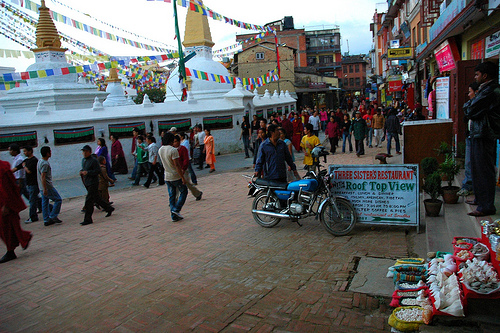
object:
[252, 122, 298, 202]
man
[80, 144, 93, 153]
cap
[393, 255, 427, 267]
bags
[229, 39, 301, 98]
building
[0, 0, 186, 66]
sky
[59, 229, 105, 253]
walkway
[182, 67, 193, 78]
banners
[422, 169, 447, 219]
display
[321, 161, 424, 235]
sign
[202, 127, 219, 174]
woman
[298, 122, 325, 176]
boy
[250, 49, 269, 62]
window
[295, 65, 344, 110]
buildings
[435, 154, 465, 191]
plants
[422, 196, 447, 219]
pots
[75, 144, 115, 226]
men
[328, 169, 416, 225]
poster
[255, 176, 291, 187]
seat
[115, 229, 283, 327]
floor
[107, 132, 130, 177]
people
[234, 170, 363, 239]
motorbike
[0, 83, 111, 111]
squares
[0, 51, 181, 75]
rope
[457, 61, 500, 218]
people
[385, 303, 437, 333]
baskets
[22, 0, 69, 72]
steeple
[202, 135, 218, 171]
orange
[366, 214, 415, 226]
arrow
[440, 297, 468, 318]
items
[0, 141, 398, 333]
road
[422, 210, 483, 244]
staircase